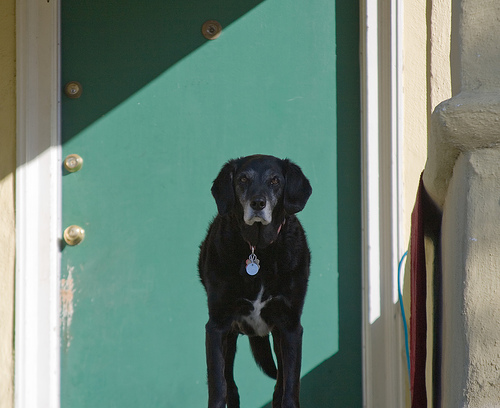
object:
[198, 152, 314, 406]
dog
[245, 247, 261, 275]
dog tag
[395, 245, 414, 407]
wire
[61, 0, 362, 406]
door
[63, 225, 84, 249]
door knob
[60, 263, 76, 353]
scratch marks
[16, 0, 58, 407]
molding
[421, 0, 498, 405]
support beam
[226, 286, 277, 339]
white stripes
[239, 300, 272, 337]
underbelly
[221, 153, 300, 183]
hair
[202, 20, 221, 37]
peephole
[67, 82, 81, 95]
deadbolt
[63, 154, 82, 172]
deadbolt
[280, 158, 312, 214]
ear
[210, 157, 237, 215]
ear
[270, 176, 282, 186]
eyes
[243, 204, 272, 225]
mouth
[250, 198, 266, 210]
nose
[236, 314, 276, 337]
stomach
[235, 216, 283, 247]
collar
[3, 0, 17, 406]
wall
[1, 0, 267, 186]
shade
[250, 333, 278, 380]
tail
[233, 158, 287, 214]
face